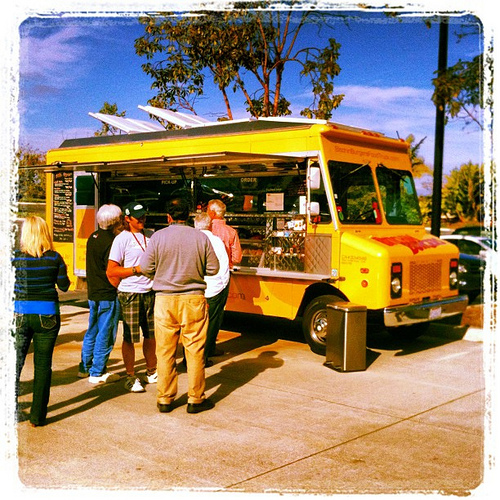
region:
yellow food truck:
[40, 103, 475, 355]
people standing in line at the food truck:
[12, 196, 242, 428]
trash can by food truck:
[317, 296, 377, 385]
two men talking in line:
[104, 197, 219, 417]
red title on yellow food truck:
[354, 227, 461, 264]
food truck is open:
[72, 156, 336, 268]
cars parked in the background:
[422, 211, 499, 281]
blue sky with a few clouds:
[16, 29, 466, 128]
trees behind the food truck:
[127, 13, 482, 116]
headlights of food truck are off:
[382, 258, 464, 299]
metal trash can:
[316, 291, 386, 385]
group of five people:
[80, 192, 250, 426]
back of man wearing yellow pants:
[145, 189, 221, 424]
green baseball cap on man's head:
[119, 197, 151, 234]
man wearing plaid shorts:
[110, 198, 165, 397]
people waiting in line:
[148, 151, 263, 430]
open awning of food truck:
[30, 133, 362, 218]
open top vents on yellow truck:
[40, 91, 435, 183]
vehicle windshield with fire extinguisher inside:
[321, 142, 452, 239]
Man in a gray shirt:
[142, 198, 233, 415]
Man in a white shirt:
[111, 203, 191, 392]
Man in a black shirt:
[75, 198, 130, 376]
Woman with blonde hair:
[16, 206, 89, 416]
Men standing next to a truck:
[73, 187, 291, 428]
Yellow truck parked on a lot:
[48, 111, 457, 374]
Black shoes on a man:
[142, 384, 229, 424]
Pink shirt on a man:
[189, 194, 256, 270]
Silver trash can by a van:
[315, 288, 386, 394]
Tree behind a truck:
[133, 11, 363, 136]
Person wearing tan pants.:
[138, 325, 233, 435]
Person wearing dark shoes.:
[167, 389, 224, 427]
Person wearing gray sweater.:
[138, 220, 225, 309]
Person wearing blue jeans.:
[77, 316, 144, 408]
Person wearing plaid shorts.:
[123, 300, 160, 369]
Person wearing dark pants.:
[30, 339, 93, 444]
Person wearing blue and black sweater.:
[38, 264, 89, 379]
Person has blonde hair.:
[24, 217, 71, 297]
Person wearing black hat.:
[98, 185, 183, 266]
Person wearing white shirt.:
[214, 277, 228, 283]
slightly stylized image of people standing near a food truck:
[0, 0, 499, 497]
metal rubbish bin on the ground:
[318, 292, 370, 378]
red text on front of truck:
[371, 224, 446, 269]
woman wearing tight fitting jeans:
[15, 310, 64, 425]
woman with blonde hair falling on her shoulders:
[17, 207, 55, 263]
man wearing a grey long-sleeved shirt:
[137, 196, 219, 292]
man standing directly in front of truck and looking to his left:
[196, 189, 243, 361]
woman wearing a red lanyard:
[111, 199, 154, 276]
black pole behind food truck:
[411, 13, 452, 334]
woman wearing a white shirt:
[107, 198, 159, 298]